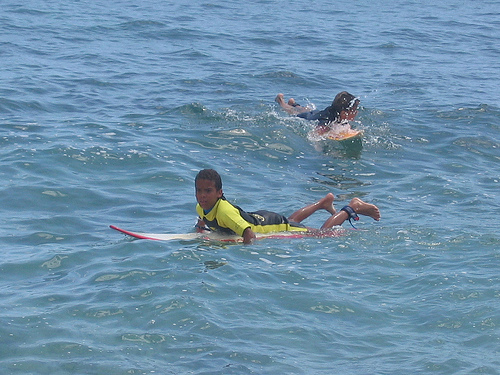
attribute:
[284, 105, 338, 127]
clothing — dark